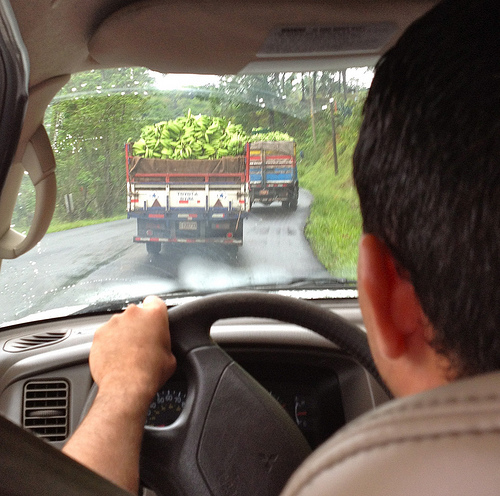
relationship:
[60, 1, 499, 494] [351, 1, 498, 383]
man has hair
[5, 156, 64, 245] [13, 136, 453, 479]
white handle in car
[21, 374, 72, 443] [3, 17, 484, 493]
vent in car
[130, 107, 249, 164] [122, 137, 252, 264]
green bananas in truck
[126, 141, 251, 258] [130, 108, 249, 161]
car carrying bananas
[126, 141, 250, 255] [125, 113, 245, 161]
car transporting bananas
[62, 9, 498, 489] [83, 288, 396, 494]
person holding steering wheel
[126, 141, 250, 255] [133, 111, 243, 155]
car carrying bananas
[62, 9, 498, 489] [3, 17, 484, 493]
person driving car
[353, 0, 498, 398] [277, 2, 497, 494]
head of person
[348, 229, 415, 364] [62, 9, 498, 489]
ear of person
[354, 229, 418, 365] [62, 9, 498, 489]
ear of person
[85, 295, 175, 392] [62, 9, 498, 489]
hand of person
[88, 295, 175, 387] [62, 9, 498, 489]
hand of person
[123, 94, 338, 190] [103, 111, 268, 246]
back of truck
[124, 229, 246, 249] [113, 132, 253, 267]
bumper of truck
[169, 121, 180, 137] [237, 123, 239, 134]
bundle of banana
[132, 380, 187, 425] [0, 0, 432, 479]
speedometer of car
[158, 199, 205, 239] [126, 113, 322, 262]
liscence plate of truck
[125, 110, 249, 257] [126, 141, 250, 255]
bananas trailer in car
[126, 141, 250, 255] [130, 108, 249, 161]
car hauling bananas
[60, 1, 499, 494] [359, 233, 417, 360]
man left ear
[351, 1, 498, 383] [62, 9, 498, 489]
hair of person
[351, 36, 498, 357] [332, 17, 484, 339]
hair of person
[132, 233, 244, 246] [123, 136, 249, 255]
bumper of a truck